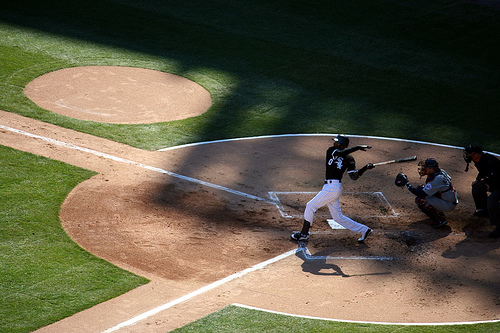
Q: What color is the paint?
A: White.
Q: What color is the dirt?
A: Brown.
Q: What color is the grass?
A: Green.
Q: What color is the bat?
A: Black.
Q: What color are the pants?
A: White.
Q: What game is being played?
A: Baseball.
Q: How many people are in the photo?
A: 3.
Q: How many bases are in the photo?
A: One.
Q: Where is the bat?
A: In the air.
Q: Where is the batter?
A: In the batter's box.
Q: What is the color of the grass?
A: Green.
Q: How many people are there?
A: Three.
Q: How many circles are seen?
A: Two.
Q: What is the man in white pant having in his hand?
A: Bat.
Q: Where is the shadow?
A: Ground.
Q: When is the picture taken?
A: Daytime.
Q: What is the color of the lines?
A: White.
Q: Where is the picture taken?
A: At a baseball park.